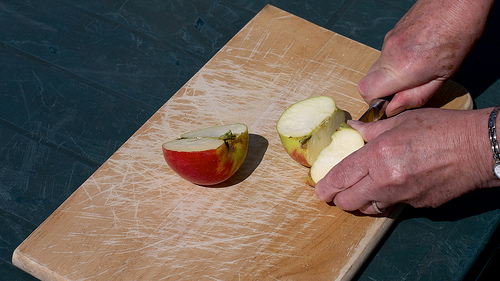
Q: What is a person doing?
A: Cutting apples.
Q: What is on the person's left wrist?
A: A watch.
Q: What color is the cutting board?
A: Light brown.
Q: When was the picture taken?
A: Before dinner.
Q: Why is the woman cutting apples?
A: For a snack.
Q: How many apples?
A: 1.